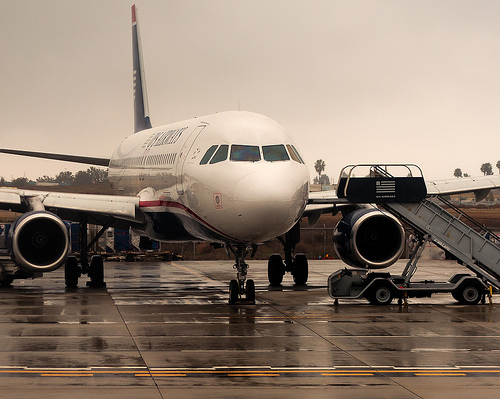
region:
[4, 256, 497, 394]
parked plane on wet gray ground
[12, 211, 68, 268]
metal ring around dark space of engine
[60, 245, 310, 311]
blocks in front of black wheels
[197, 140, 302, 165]
angled windows in front of plane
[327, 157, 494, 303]
ramp on wheeled platform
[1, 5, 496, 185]
light gray skies behind plane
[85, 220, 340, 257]
metal fence behind plane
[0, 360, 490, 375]
yellow and white stripes in front of plane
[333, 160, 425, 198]
gray railing curved over black partitions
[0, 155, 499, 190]
trees behind wings of plane in distance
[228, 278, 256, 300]
front landing gear tires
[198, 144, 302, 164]
multiple windshield windows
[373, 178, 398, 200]
logo on the stairs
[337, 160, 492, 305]
portable loading stairs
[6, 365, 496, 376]
yellow lines on the runway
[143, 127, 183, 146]
airline logo on the plane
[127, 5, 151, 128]
rear tale on the plane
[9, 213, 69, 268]
engine on plane wing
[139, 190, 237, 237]
red accent stripe on the plane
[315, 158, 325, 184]
tall palm tree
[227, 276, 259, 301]
Front wheels on a plane.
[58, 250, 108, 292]
Back wheels on the plane.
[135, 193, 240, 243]
Red stripe on plane.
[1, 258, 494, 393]
Wet pavement on the ground.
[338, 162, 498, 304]
Stairs for boarding the plane.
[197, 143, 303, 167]
Front windows on the plane.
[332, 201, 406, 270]
Engine on the plane.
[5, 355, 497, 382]
Yellow and white lines on the plane.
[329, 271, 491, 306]
Wheels on the stairs.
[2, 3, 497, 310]
Airplane in the forefront.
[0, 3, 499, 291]
an airplane on the ground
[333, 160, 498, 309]
stairway to get onto plane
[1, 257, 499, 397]
wet ground under plane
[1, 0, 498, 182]
a grey white sky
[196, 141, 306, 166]
front windows of plane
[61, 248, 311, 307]
landing wheels of plane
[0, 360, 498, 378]
yellow and white lines on ground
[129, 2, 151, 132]
blue tail fin of plane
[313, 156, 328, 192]
one tree with bushy round top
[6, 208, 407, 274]
engines of plane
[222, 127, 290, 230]
white nose on plane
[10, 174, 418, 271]
black engines on plane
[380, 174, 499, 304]
grey steps leading to plane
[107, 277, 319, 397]
grey tarmac under plane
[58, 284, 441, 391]
grey tarmac is wet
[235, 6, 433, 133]
sky is grey and cloudy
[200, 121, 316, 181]
rectangular windows on plane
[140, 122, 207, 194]
blue name on side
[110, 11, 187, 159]
red white and blue tail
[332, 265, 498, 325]
wheels on step ladder